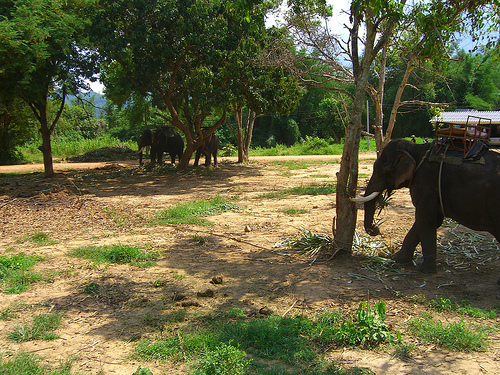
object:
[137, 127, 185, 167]
elephants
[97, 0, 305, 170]
trees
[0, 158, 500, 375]
dirt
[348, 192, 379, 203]
tusks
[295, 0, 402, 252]
tree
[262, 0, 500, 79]
sky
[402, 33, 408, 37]
leaves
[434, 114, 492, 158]
bench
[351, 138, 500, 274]
elephant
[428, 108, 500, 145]
building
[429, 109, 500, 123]
roof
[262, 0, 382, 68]
clouds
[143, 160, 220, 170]
shade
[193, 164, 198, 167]
feet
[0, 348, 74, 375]
grass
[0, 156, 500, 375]
ground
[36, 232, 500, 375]
shadow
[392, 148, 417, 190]
ear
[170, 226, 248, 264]
sand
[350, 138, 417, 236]
head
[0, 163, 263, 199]
shadow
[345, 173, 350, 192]
mark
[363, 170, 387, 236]
trunk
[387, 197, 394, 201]
leaves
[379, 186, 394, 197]
mouth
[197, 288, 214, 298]
droppings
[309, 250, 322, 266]
leaves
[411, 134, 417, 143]
people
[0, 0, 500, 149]
background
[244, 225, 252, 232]
rock